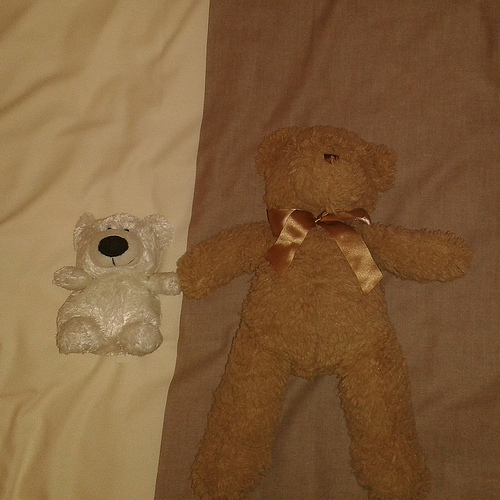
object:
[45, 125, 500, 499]
bears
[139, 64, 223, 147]
bed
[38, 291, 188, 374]
legs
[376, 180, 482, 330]
arm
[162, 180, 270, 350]
arm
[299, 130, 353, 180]
nose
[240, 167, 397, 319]
bow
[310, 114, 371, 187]
nose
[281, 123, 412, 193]
eyes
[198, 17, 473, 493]
fabric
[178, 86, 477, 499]
bear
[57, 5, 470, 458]
blanket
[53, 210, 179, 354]
bear toy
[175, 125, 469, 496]
bear toy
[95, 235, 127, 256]
bear nose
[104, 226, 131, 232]
eyes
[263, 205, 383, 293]
ribbon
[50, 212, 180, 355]
bear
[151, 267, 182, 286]
limb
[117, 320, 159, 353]
limb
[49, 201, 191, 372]
animal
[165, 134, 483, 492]
animal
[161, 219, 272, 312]
limb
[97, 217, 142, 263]
nose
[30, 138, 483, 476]
bear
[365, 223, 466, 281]
limb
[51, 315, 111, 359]
limb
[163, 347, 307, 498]
leg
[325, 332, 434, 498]
leg